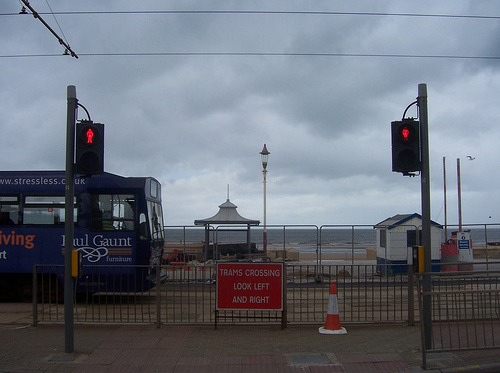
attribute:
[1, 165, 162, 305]
bus — white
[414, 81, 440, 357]
pole — electric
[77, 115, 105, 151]
light — red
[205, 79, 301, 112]
sky — cloudy, grey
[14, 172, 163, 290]
tram — blue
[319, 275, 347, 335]
traffic cone — orange, white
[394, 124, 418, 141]
sign — red, white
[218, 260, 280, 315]
sign — red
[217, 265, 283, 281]
text — white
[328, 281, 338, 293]
cone — orange, white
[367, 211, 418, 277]
building — white, blue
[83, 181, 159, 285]
bus — blue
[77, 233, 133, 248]
print — white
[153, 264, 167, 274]
post — metal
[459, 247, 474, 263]
board — red, white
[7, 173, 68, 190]
advertisement — displayed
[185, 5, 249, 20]
wires — small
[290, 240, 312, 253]
water — blue